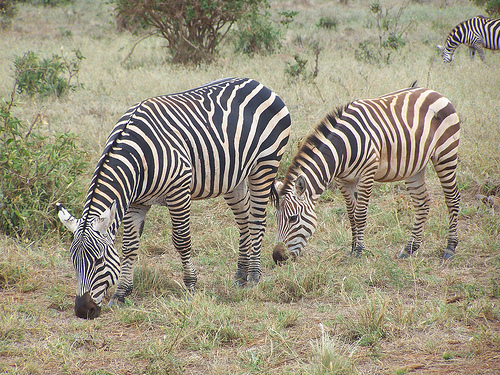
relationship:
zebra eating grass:
[285, 96, 467, 265] [196, 310, 284, 352]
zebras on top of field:
[93, 77, 472, 293] [301, 48, 400, 92]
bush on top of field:
[278, 53, 304, 81] [301, 48, 400, 92]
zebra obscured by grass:
[285, 96, 467, 265] [196, 310, 284, 352]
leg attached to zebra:
[357, 190, 370, 252] [285, 96, 467, 265]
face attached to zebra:
[52, 198, 116, 307] [285, 96, 467, 265]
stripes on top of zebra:
[168, 98, 207, 194] [285, 96, 467, 265]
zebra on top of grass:
[285, 96, 467, 265] [196, 310, 284, 352]